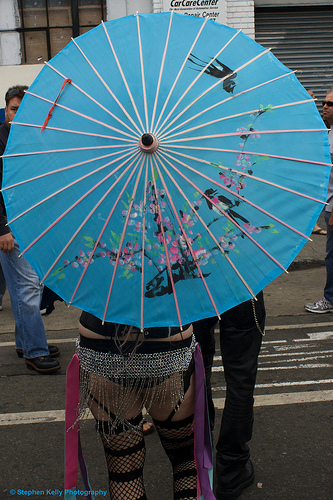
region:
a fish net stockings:
[94, 421, 150, 497]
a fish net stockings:
[151, 403, 221, 499]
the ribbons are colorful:
[47, 354, 98, 497]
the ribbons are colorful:
[185, 336, 243, 498]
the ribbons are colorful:
[176, 345, 213, 494]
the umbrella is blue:
[11, 80, 274, 327]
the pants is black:
[177, 285, 255, 491]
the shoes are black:
[13, 339, 71, 388]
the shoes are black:
[212, 439, 270, 498]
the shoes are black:
[18, 328, 60, 374]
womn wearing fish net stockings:
[63, 335, 218, 497]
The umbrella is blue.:
[7, 15, 327, 319]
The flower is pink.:
[168, 242, 176, 256]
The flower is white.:
[198, 249, 210, 261]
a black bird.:
[182, 51, 242, 104]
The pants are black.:
[196, 305, 259, 491]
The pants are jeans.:
[0, 240, 48, 359]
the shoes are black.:
[19, 341, 58, 378]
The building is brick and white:
[151, 0, 251, 36]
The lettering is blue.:
[8, 486, 105, 496]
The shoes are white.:
[305, 294, 327, 319]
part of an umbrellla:
[254, 154, 269, 168]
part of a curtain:
[203, 461, 208, 466]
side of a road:
[268, 430, 285, 455]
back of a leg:
[136, 465, 139, 470]